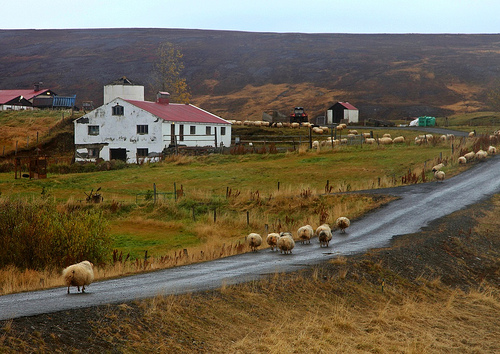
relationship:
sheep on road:
[63, 260, 94, 294] [0, 123, 500, 322]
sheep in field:
[392, 135, 405, 144] [0, 0, 498, 352]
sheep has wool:
[63, 260, 94, 294] [63, 259, 94, 286]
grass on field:
[0, 29, 499, 352] [0, 0, 498, 352]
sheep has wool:
[277, 235, 297, 255] [278, 236, 295, 250]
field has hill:
[0, 0, 498, 352] [0, 28, 499, 133]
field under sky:
[0, 0, 498, 352] [0, 0, 499, 33]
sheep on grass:
[348, 128, 359, 136] [0, 29, 499, 352]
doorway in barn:
[108, 147, 127, 162] [75, 91, 233, 163]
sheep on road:
[318, 229, 333, 247] [0, 123, 500, 322]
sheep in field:
[377, 137, 393, 145] [0, 0, 498, 352]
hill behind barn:
[0, 28, 499, 133] [75, 91, 233, 163]